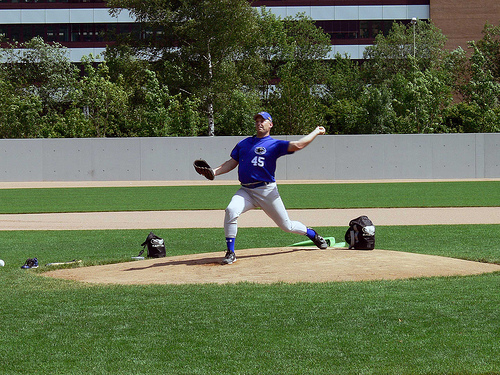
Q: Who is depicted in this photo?
A: A baseball player.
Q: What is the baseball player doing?
A: Pitching.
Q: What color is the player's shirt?
A: Blue.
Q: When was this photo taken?
A: Daytime.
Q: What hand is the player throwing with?
A: His left hand.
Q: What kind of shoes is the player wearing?
A: Cleats.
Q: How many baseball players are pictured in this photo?
A: One.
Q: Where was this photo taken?
A: Baseball field.